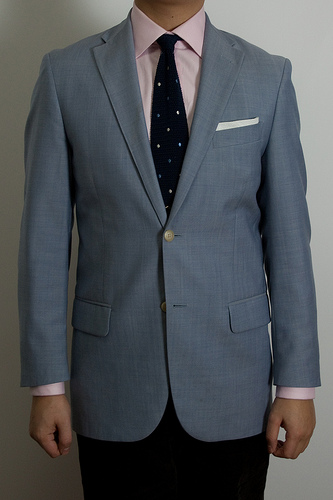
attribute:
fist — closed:
[5, 391, 88, 476]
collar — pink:
[131, 4, 205, 57]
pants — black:
[64, 398, 288, 499]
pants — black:
[78, 395, 274, 497]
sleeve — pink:
[30, 382, 63, 396]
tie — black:
[150, 30, 190, 217]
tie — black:
[149, 33, 186, 207]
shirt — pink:
[129, 6, 206, 113]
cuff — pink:
[270, 383, 322, 406]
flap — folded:
[226, 291, 270, 335]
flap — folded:
[71, 296, 112, 338]